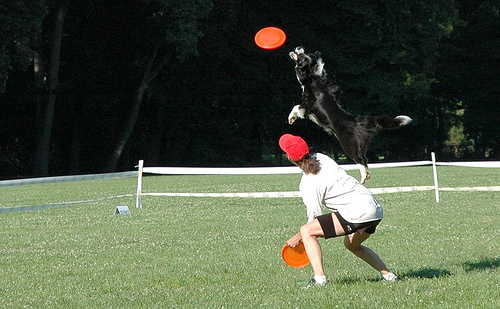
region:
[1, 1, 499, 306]
an outdoor image of a Frisbee competition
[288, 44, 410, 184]
a black and white dog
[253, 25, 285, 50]
an orange colored Frisbee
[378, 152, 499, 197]
a white jumping fence for the dogs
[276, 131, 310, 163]
this person is wearing a red cap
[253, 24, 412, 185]
the dog is jumping for the Frisbee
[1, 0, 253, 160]
a shady area of trees and shrubs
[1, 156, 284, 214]
white fence and markers marking the boundaries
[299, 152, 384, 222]
the person is wearing a white t-shirt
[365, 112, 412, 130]
the dogs tail has a white tip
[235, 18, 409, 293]
a person playing frisbee with a dog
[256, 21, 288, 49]
a red frisbee in the air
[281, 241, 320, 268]
a red frisbee the person is holding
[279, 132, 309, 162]
a red ball cap on the person's head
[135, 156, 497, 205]
a white fence behind the person and the dog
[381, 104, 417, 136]
the dog's black and white tail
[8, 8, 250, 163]
a dark forest of trees in the background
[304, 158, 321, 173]
long brown hair on the person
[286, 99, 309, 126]
the dog's front curled white paw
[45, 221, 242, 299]
very green lush grass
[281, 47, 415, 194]
a dog jumping up to get a frisbee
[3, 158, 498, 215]
the fence in the middle of the field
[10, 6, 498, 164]
the trees at the end of the field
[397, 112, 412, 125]
the white tip of the dog's tail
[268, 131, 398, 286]
the woman playing with the dog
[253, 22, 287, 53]
the frisbee the dog is reaching for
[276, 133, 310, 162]
the red hat the woman is wearing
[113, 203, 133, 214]
the piece of paper on the ground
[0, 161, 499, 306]
the green grass on the ground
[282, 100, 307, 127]
the white paws of the dog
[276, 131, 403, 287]
woman wearing white thsirt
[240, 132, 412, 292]
woman in white shoes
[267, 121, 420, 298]
woman wearing white socks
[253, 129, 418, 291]
woman wears red had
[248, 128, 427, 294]
woman has orange fristbee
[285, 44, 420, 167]
black and white dog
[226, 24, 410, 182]
dog is jumping after frisbbee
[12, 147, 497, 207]
white fence in green grass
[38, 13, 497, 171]
large trees in background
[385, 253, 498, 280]
shadow cast by woman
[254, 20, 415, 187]
A collie leaping for a frisby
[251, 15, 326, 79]
An orange frisbie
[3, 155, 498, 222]
A white fence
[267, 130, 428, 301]
A woman in a red hat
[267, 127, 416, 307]
A woman preparing to throw a Frisbee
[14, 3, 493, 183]
Tall trees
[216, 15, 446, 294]
Playing fetch on a sunny day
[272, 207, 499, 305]
Long shadows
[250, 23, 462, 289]
An impressive vertical leap by a border collie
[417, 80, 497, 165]
A path through the trees